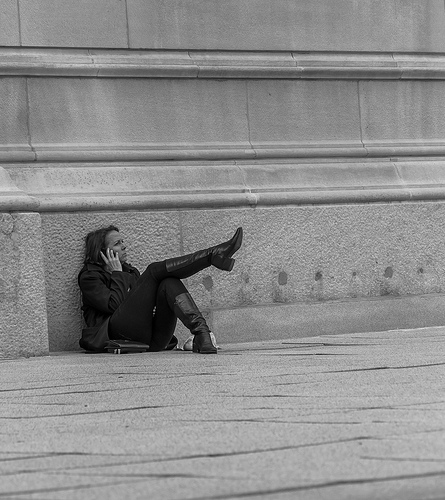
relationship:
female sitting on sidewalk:
[77, 225, 243, 355] [1, 323, 442, 497]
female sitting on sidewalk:
[77, 225, 243, 355] [51, 334, 421, 460]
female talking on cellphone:
[77, 225, 243, 355] [82, 233, 146, 283]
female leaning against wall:
[77, 225, 243, 355] [282, 203, 320, 274]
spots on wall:
[197, 258, 430, 299] [0, 2, 443, 499]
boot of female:
[173, 291, 218, 357] [77, 225, 243, 355]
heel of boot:
[222, 255, 247, 274] [168, 233, 246, 283]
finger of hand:
[99, 249, 108, 262] [98, 246, 122, 273]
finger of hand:
[105, 247, 109, 258] [99, 249, 124, 271]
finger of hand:
[99, 249, 107, 260] [99, 249, 124, 271]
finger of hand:
[110, 248, 115, 257] [99, 249, 124, 271]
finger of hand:
[114, 251, 119, 257] [99, 249, 124, 271]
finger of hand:
[109, 246, 116, 261] [97, 246, 127, 275]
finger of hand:
[99, 249, 108, 262] [91, 245, 130, 273]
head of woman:
[83, 225, 127, 262] [77, 222, 243, 354]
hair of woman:
[84, 225, 119, 260] [77, 222, 243, 354]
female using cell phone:
[77, 225, 243, 355] [98, 246, 120, 263]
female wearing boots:
[77, 225, 243, 355] [164, 228, 249, 271]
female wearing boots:
[77, 225, 243, 355] [168, 294, 216, 353]